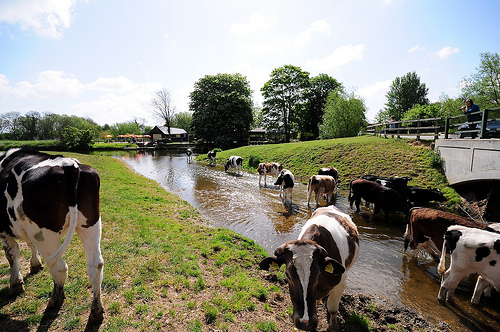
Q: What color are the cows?
A: Black, white, and brown.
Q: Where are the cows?
A: On the grass and in the water.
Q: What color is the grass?
A: Green.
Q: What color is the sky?
A: Blue.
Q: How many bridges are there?
A: One.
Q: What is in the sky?
A: Clouds.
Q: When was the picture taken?
A: Daytime.